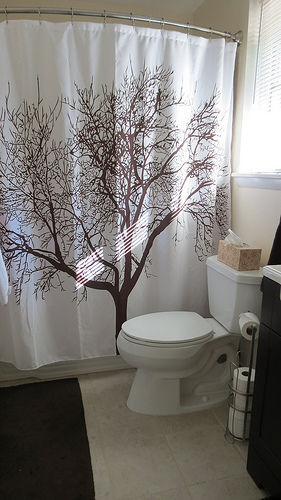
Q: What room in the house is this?
A: Bathroom.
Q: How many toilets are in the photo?
A: One.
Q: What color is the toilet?
A: White.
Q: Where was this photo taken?
A: Bathroom.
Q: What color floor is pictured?
A: White.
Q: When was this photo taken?
A: Day time.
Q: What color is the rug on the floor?
A: Brown.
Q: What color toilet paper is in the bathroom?
A: White.